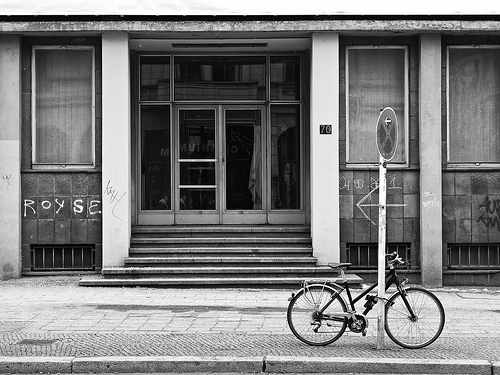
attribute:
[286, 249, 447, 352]
bike — black, parked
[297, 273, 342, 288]
cargo rack — silver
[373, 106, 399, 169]
sign — informative, round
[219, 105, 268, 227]
office door — glass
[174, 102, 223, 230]
office door — glass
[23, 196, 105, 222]
grafitti — white, spray painted, painted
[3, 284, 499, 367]
sidewalk — brick, paved, stone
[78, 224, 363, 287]
stairs — cement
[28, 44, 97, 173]
window — tall, glass, barred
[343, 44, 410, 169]
window — tall, glass, barred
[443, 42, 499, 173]
window — tall, glass, barred